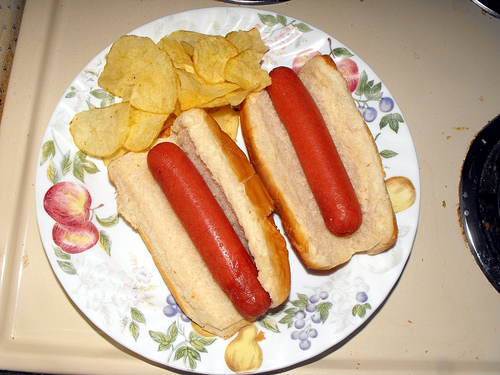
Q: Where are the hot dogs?
A: Plate.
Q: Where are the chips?
A: Plate.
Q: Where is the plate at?
A: Counter.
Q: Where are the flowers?
A: Plate.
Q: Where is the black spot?
A: On right.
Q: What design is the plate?
A: Floral.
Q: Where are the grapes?
A: Plate.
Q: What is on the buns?
A: Hot dogs.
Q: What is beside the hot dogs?
A: Chips.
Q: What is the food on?
A: Plate.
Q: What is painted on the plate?
A: Fruit and leaves.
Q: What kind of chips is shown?
A: Plain.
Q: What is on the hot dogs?
A: Nothing.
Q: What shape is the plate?
A: Round.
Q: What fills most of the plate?
A: Hot dog buns.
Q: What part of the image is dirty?
A: Tray under the plate.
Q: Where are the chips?
A: Plate.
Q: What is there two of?
A: Hot dogs.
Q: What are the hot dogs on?
A: Plate.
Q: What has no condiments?
A: Hot dogs.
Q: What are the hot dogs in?
A: Bun.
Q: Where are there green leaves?
A: Plate.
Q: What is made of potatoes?
A: Chips.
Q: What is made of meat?
A: Hot dogs.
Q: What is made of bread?
A: Buns.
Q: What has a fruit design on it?
A: Plate.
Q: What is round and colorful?
A: Plate.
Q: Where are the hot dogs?
A: In two buns.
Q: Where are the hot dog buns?
A: On the plate.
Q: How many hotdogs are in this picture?
A: Two.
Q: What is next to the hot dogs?
A: Chips.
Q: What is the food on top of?
A: A plate.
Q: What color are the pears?
A: Brown.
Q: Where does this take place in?
A: Kitchen.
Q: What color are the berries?
A: Blue.